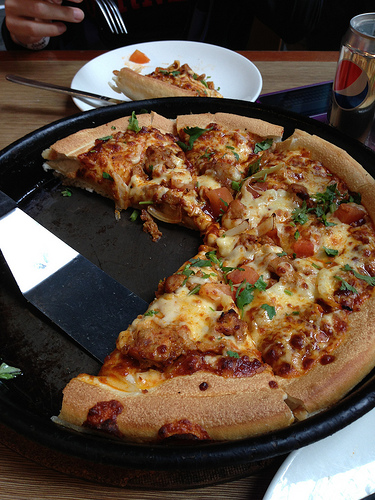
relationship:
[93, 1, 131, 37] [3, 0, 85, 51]
fork in hand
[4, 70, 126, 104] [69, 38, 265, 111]
knife on plate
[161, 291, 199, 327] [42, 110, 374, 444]
cheese on pizza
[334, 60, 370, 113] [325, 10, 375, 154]
logo on can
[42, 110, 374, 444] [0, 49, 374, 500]
pizza on table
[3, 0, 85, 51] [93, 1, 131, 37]
hand holding fork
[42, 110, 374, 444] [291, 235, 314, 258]
pizza has tomatoe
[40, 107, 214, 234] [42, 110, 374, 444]
slice of pizza